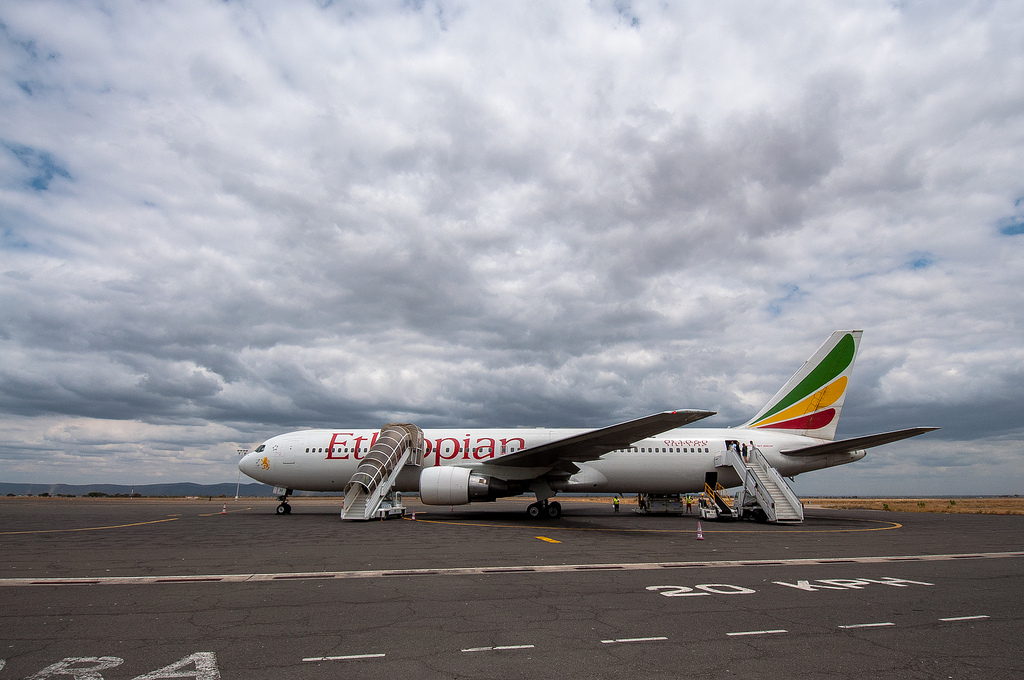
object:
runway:
[0, 495, 1024, 680]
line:
[600, 636, 668, 643]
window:
[655, 448, 660, 453]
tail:
[728, 328, 863, 440]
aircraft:
[238, 327, 944, 524]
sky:
[0, 0, 1024, 506]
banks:
[98, 206, 774, 323]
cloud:
[0, 314, 1024, 442]